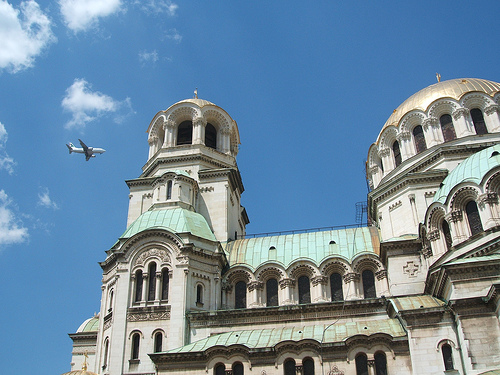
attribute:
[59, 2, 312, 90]
sky — blue, here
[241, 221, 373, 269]
roof — gold, green, rusty, tarnished, edged, here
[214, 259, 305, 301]
window — here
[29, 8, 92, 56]
cloud — here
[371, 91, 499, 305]
building — stone, tan, green, gold, large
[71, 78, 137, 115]
clouds — small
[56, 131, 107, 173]
plane — flying, close, commercial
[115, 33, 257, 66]
sun — out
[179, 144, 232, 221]
ladder — atop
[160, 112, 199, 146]
arches — above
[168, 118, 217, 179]
doors — above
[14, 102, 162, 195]
airplane — whie, flying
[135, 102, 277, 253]
tower — small